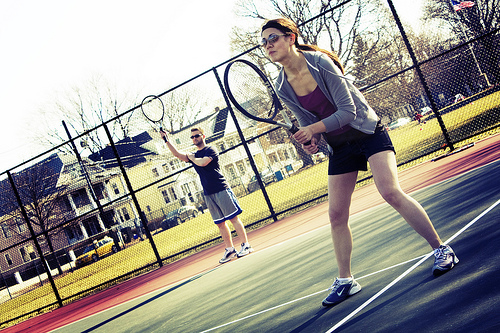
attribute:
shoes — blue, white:
[320, 272, 367, 310]